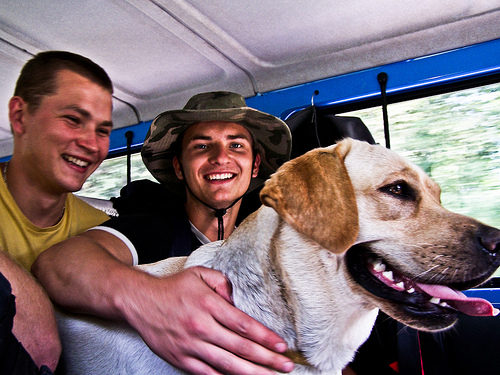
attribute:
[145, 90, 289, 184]
hat — camo, floppy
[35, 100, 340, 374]
man — smiling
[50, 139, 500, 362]
dog — golden retriever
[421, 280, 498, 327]
tongue — pink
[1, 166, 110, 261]
shirt — yellow, black, white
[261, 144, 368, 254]
ear — brown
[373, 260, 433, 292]
teeth — white, sharp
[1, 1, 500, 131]
ceiling — gray